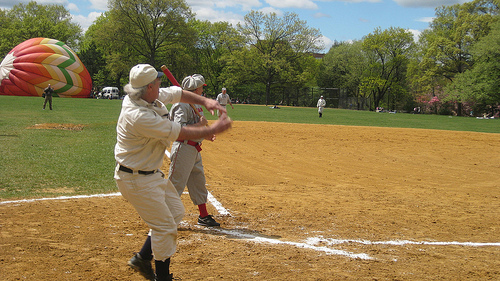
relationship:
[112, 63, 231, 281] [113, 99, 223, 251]
man wearing uniforms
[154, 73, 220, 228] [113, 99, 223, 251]
batter wearing uniforms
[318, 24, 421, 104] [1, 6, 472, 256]
tree lining park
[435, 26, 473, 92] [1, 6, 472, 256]
tree lining park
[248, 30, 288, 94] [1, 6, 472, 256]
tree lining park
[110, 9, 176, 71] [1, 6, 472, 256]
tree lining park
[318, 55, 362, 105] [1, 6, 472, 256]
tree lining park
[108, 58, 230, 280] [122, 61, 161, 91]
man wearing white hat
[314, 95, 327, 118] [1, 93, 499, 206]
person standing grass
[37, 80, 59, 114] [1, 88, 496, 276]
player in field